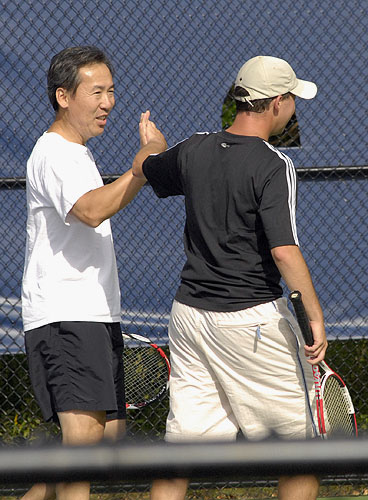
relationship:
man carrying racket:
[20, 42, 151, 500] [289, 286, 355, 457]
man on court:
[130, 51, 329, 500] [2, 282, 349, 484]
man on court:
[20, 42, 151, 500] [2, 282, 349, 484]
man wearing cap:
[136, 51, 329, 495] [232, 53, 317, 105]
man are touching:
[20, 42, 151, 500] [129, 108, 170, 184]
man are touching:
[130, 51, 329, 500] [129, 108, 170, 184]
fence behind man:
[2, 0, 367, 493] [19, 44, 153, 498]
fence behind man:
[2, 0, 367, 493] [136, 51, 329, 495]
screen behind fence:
[4, 27, 356, 336] [3, 5, 352, 443]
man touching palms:
[130, 51, 329, 500] [134, 108, 167, 175]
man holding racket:
[130, 51, 329, 500] [110, 297, 174, 416]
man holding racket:
[130, 51, 329, 500] [289, 286, 355, 457]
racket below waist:
[289, 286, 355, 457] [16, 307, 143, 397]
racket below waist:
[289, 286, 355, 457] [160, 272, 307, 360]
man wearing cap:
[136, 51, 329, 495] [232, 53, 317, 100]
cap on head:
[232, 53, 317, 100] [230, 55, 297, 137]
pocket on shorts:
[218, 321, 257, 333] [145, 289, 324, 476]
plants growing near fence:
[6, 317, 354, 480] [142, 20, 192, 81]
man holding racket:
[136, 51, 329, 495] [289, 289, 358, 442]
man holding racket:
[20, 42, 151, 500] [118, 333, 163, 415]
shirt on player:
[24, 132, 133, 330] [144, 37, 335, 402]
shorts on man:
[22, 319, 128, 425] [20, 42, 151, 500]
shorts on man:
[158, 297, 337, 444] [130, 51, 329, 500]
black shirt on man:
[158, 127, 298, 309] [130, 51, 329, 500]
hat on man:
[233, 54, 318, 93] [130, 51, 329, 500]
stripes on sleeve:
[260, 138, 305, 245] [257, 157, 306, 248]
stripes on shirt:
[260, 138, 305, 245] [142, 125, 302, 311]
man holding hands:
[20, 46, 124, 494] [120, 108, 169, 196]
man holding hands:
[136, 51, 329, 495] [120, 108, 169, 196]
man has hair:
[20, 42, 151, 500] [47, 44, 115, 112]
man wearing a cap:
[136, 51, 329, 495] [232, 53, 317, 105]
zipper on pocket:
[253, 322, 264, 340] [212, 312, 269, 336]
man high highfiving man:
[130, 51, 329, 500] [32, 49, 127, 334]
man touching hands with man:
[136, 51, 329, 495] [19, 44, 153, 498]